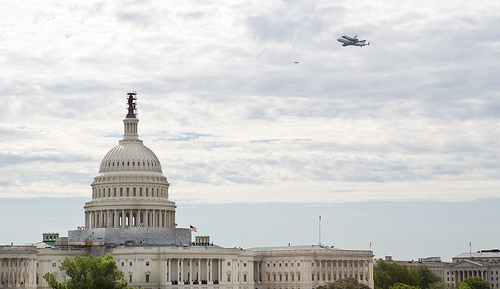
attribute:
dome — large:
[80, 85, 181, 230]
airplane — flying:
[331, 30, 374, 52]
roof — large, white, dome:
[101, 124, 176, 164]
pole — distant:
[315, 212, 327, 249]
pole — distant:
[462, 239, 477, 256]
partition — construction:
[69, 226, 199, 247]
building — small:
[442, 252, 499, 287]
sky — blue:
[0, 0, 498, 249]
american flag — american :
[182, 222, 198, 231]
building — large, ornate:
[13, 88, 376, 285]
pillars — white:
[307, 261, 365, 286]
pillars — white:
[80, 204, 176, 228]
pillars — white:
[165, 256, 220, 284]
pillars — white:
[262, 263, 306, 285]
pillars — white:
[123, 122, 139, 135]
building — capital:
[45, 83, 359, 281]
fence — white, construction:
[66, 224, 194, 246]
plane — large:
[331, 25, 376, 58]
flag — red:
[187, 222, 199, 234]